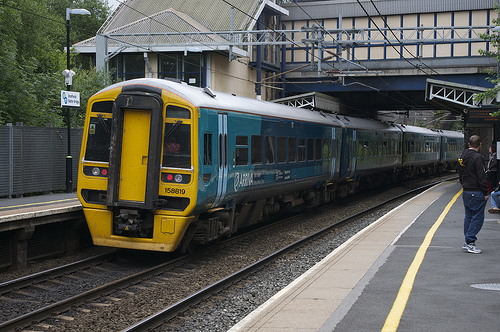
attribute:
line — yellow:
[380, 188, 461, 329]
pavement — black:
[332, 180, 499, 330]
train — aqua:
[52, 35, 447, 261]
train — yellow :
[81, 73, 203, 253]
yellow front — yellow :
[75, 78, 192, 257]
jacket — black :
[458, 145, 490, 190]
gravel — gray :
[133, 189, 428, 330]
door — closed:
[99, 92, 171, 211]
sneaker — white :
[464, 242, 480, 254]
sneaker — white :
[460, 241, 466, 250]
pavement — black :
[230, 173, 499, 330]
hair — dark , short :
[467, 132, 487, 147]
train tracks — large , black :
[0, 155, 467, 330]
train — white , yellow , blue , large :
[80, 76, 471, 253]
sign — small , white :
[48, 84, 80, 109]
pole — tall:
[62, 0, 78, 191]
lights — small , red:
[81, 144, 302, 212]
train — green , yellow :
[72, 69, 487, 258]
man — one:
[455, 134, 490, 251]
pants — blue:
[459, 188, 487, 244]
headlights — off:
[63, 157, 191, 191]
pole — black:
[62, 18, 72, 188]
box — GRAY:
[61, 68, 74, 85]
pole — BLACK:
[62, 18, 73, 192]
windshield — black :
[87, 113, 117, 163]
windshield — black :
[164, 119, 190, 171]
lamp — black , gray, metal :
[59, 5, 94, 194]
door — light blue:
[214, 113, 228, 208]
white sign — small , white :
[187, 74, 198, 88]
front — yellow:
[74, 74, 203, 256]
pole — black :
[59, 3, 80, 190]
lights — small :
[85, 159, 187, 183]